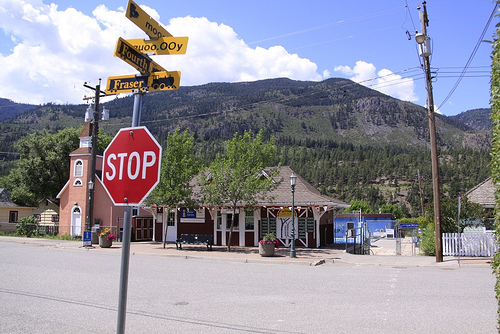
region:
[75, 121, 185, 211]
stop road sign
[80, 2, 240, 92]
yellow directional road signs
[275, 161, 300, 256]
sidewalk street light post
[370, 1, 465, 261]
wooden electrical utility pole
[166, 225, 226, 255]
green bench between trees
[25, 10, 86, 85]
white clouds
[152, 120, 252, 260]
pair of green trees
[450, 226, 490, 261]
wooden white picket fence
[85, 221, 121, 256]
multi colored flowers in planter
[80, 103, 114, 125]
electrical transformer on utlity pole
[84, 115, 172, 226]
A red and white STOP sign.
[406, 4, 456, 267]
An electric power pole.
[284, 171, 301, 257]
A streetlight.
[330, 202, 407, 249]
A blue small building in the back.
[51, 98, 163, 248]
A light red colored church.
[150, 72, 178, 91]
A black train on a sign.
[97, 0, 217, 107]
Black and yellow street signs.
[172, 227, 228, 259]
A dark colored bench.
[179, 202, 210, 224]
A sign on the wall of a red building.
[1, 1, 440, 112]
White and puffy clouds in the sky.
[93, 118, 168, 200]
Red and white stop sign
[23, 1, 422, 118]
White fluffy clouds behind mountain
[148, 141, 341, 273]
A little store on the corner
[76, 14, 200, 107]
four yellow and black signs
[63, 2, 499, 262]
Two light poles on other side of street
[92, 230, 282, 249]
Two flower planters in front of store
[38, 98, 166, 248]
A little red church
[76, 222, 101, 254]
Blue sign at bottom of pole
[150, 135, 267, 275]
Two trees in front of store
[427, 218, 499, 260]
A white picket fence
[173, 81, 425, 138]
the hills have few trees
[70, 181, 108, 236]
the building is brown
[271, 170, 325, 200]
the roof is grey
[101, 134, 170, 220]
the stop sign is an octagon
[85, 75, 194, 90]
the street is fraser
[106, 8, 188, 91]
the sign posts are yellow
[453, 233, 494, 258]
the fence is white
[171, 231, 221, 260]
the bench has nobody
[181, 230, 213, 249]
the bench is grey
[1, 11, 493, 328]
the scene is an outdoor scene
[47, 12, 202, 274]
a sign stop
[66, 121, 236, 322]
a sign stop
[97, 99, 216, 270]
a sign stop